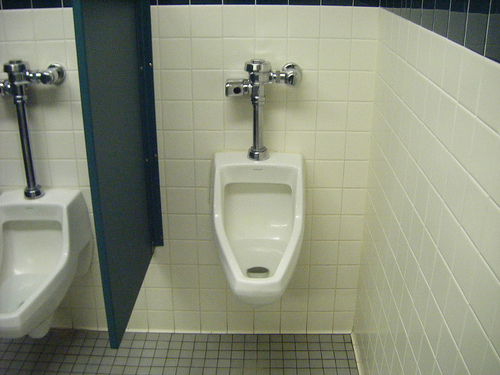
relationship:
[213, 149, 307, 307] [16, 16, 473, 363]
toilet in bathroom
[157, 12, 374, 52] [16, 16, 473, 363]
tile of bathroom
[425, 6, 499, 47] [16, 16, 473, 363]
tile of bathroom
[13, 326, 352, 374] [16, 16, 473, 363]
tile for bathroom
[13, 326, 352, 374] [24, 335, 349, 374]
tile for floor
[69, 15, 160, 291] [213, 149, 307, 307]
divider between toilet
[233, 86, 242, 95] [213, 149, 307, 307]
motion censor on toilet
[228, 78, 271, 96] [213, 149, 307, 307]
flushing apparatus of toilet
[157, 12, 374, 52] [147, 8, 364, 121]
tile on wall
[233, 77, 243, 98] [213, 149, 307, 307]
motion censor on toilet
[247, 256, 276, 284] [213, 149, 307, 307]
water in toilet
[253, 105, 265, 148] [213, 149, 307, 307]
water pipe into toilet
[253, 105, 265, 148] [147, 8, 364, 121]
water pipe into wall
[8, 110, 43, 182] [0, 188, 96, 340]
water pipe for toilet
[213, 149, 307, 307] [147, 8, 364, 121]
toilet attached to wall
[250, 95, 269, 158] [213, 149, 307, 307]
pipes on toilet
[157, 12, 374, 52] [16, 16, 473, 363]
tile in bathroom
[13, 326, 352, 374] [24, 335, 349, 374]
tile on floor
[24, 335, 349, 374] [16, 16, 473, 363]
floor in bathroom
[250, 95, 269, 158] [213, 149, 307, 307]
pipes attached to toilet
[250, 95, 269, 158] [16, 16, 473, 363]
pipes in bathroom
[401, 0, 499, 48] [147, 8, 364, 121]
tiles around wall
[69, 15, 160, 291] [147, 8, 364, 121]
divider attached to wall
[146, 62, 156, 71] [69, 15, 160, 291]
screws attach divider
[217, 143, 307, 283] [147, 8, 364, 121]
toilet on wall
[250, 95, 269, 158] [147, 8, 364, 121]
pipes attached to wall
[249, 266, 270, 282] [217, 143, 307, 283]
hole in toilet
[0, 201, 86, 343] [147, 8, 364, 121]
toilet on wall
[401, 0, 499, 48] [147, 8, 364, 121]
tiles on wall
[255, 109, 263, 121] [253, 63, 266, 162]
light on silver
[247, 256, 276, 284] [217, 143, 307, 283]
water in toilet